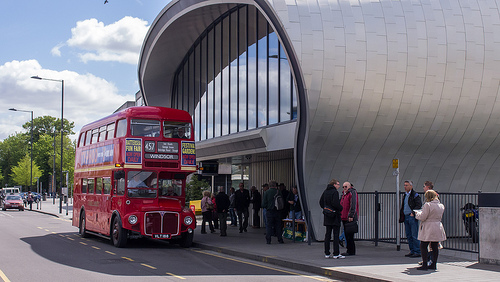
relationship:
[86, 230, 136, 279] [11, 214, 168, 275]
lines on street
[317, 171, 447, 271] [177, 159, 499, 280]
men/women standing at bus stop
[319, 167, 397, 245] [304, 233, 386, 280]
woman standing on sidewalk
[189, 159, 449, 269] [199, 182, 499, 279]
people standing on sidewalk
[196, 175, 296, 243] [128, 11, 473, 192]
people near building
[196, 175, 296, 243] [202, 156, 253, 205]
people near entrance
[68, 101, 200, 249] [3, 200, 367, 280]
bus on street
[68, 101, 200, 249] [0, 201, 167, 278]
bus on street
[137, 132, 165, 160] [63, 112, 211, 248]
front number printed on bus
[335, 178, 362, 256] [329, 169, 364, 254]
he wearing jacket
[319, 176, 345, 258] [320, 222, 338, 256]
person in dark pants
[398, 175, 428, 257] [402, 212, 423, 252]
person wearing dark pants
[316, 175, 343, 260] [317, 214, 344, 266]
person wears dark pants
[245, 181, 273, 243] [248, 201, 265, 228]
person wearing dark pants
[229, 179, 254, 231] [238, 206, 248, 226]
person wearing dark pants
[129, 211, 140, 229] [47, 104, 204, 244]
headlight on bus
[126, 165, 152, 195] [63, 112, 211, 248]
driver on bus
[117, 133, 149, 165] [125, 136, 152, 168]
advertisement on bus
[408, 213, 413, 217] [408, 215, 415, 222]
hand in pocket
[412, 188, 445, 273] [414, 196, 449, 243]
woman wearing jacket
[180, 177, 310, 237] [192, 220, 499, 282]
people oln sidewalk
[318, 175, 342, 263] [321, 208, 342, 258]
person wearing dark pants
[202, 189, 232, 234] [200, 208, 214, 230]
person wearing pants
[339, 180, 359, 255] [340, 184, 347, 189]
man wearing sunglasses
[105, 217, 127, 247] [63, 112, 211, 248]
wheel of bus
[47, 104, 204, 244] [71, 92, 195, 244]
bus has two stories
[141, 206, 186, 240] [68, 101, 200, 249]
grill on bus